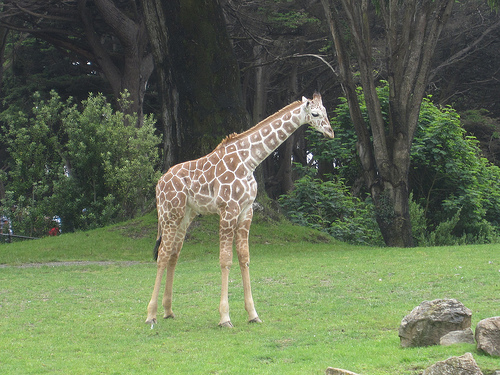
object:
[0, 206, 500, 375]
grass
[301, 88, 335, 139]
head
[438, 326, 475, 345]
rocks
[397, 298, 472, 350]
rock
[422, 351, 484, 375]
rock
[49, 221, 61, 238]
person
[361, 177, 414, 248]
tree trunk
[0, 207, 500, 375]
ground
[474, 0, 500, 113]
trees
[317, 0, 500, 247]
grouping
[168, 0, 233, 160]
moss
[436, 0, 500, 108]
tree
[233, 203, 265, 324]
leg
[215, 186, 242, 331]
leg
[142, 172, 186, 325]
leg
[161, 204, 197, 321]
leg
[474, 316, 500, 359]
rock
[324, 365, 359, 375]
rock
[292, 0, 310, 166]
tree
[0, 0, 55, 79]
tree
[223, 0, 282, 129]
tree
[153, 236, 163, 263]
hair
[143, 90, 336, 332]
giraffe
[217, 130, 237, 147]
brown mane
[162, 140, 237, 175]
back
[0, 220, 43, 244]
fence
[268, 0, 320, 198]
tree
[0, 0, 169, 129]
tree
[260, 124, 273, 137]
spot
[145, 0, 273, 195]
tree trunk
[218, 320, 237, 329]
hooves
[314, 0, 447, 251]
tree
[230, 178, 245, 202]
spot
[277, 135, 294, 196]
tree trunk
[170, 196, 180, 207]
spot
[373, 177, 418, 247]
bark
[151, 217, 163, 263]
giraffe's tail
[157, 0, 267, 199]
tree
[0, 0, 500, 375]
zoo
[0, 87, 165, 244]
bush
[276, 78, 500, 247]
bush